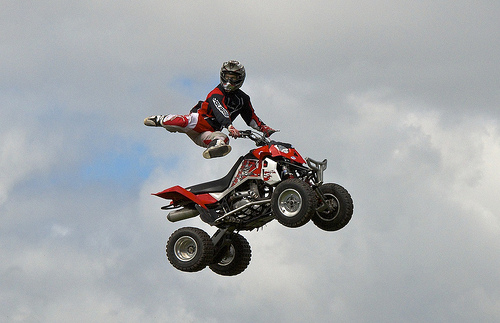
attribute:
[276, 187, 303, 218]
rim — grey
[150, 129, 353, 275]
4 wheeler — red, white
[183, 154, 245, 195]
seat — black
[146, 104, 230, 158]
pants — white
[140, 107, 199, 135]
leg — extended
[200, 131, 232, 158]
leg — extended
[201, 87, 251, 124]
top — black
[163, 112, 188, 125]
trim — red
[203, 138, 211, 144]
trim — red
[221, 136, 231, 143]
trim — red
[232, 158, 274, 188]
decal — red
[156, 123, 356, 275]
bike — red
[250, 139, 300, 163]
red — black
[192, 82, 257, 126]
top — red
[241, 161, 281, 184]
trim — white